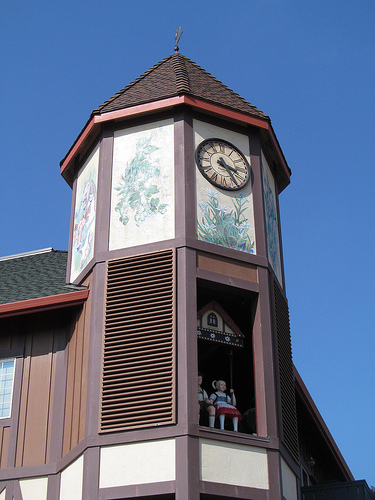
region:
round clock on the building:
[188, 133, 250, 193]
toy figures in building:
[173, 356, 250, 432]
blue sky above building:
[302, 285, 360, 358]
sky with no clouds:
[294, 266, 374, 385]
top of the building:
[103, 34, 248, 120]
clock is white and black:
[195, 135, 249, 191]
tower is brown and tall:
[60, 28, 292, 301]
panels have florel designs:
[196, 185, 255, 252]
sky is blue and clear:
[1, 1, 372, 489]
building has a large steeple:
[59, 26, 291, 196]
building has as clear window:
[0, 355, 15, 415]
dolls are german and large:
[196, 373, 241, 428]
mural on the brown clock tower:
[111, 135, 173, 236]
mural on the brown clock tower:
[196, 186, 257, 255]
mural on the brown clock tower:
[72, 171, 96, 271]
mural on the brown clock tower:
[259, 161, 280, 270]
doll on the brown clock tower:
[208, 377, 249, 434]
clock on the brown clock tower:
[196, 137, 252, 192]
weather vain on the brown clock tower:
[169, 22, 189, 51]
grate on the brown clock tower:
[97, 248, 175, 435]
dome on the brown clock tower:
[60, 51, 296, 181]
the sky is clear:
[296, 215, 368, 352]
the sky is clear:
[298, 226, 373, 364]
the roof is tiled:
[124, 68, 240, 115]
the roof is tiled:
[110, 54, 234, 114]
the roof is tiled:
[90, 70, 226, 115]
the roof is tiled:
[90, 58, 240, 111]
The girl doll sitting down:
[209, 368, 256, 429]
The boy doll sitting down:
[188, 375, 214, 424]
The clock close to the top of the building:
[187, 128, 272, 208]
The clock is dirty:
[189, 130, 258, 201]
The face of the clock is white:
[204, 142, 246, 181]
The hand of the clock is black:
[216, 157, 247, 182]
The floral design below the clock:
[195, 191, 262, 258]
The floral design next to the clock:
[112, 128, 166, 234]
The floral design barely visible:
[256, 163, 295, 284]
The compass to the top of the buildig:
[162, 23, 193, 55]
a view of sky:
[44, 31, 88, 63]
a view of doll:
[194, 373, 259, 444]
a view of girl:
[180, 293, 245, 437]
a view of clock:
[191, 145, 241, 195]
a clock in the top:
[187, 142, 268, 196]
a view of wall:
[92, 243, 228, 465]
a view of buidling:
[196, 420, 278, 489]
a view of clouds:
[305, 297, 358, 372]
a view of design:
[112, 145, 168, 238]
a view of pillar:
[42, 137, 331, 481]